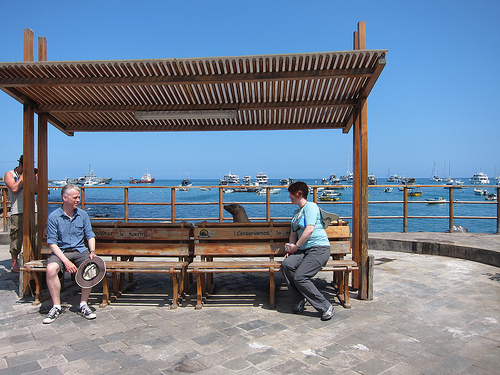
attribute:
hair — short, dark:
[288, 180, 310, 199]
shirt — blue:
[286, 199, 329, 245]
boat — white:
[124, 168, 171, 189]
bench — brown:
[187, 216, 361, 308]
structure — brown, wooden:
[8, 17, 440, 314]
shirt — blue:
[290, 200, 330, 249]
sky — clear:
[387, 22, 479, 134]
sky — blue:
[5, 0, 499, 177]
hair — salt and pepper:
[57, 177, 82, 197]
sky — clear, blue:
[392, 77, 469, 132]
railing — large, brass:
[46, 182, 498, 229]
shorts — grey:
[47, 249, 168, 299]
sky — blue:
[377, 15, 497, 173]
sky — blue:
[48, 133, 358, 174]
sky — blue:
[49, 7, 351, 54]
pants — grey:
[282, 247, 327, 302]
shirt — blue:
[46, 211, 99, 252]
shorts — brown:
[49, 248, 91, 270]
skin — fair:
[285, 189, 313, 252]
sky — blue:
[6, 0, 498, 116]